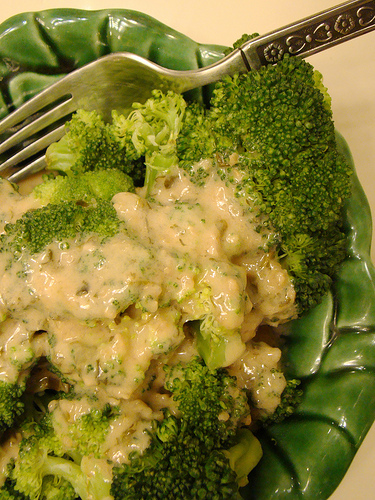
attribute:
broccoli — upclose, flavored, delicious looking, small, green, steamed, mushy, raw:
[66, 115, 323, 357]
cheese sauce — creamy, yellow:
[49, 254, 233, 382]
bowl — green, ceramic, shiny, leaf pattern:
[5, 10, 225, 104]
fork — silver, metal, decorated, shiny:
[64, 8, 371, 107]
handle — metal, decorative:
[238, 19, 372, 68]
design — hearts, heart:
[290, 26, 374, 40]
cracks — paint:
[41, 27, 77, 73]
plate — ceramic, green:
[28, 20, 374, 489]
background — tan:
[150, 0, 374, 71]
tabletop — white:
[185, 14, 374, 162]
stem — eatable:
[137, 146, 183, 202]